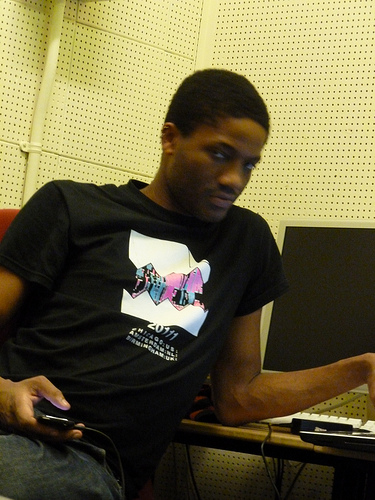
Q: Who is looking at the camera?
A: The young man.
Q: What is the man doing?
A: Sitting down.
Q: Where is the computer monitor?
A: Next to the man.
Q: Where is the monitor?
A: On the desk.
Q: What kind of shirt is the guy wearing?
A: A black t-shirt.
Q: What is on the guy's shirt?
A: A design.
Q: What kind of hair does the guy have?
A: Short.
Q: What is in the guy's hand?
A: A cellphone.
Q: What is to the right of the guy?
A: A computer screen.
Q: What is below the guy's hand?
A: A keyboard.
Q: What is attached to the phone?
A: A cord.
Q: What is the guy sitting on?
A: A chair.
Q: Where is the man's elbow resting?
A: On a desk.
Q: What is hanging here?
A: Cords.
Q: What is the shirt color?
A: Black.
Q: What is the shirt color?
A: Black.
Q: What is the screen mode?
A: Off.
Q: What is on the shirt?
A: Image.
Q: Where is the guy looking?
A: Camera.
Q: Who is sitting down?
A: The man.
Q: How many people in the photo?
A: One.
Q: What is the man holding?
A: Electronic device.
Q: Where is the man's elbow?
A: On desk.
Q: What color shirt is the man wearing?
A: Black.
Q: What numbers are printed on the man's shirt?
A: The numbers 20111.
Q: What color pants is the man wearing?
A: Gray.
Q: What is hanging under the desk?
A: Cords.